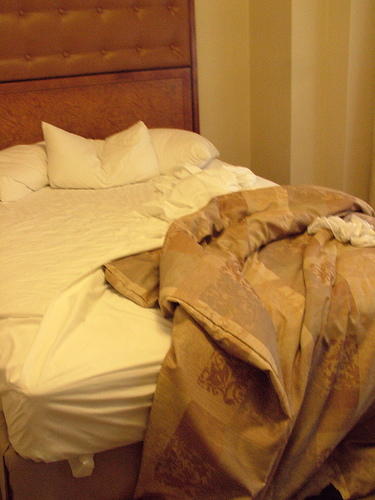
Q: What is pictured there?
A: Bed.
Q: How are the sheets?
A: Messy.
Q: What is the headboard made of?
A: Leather.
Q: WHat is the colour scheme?
A: Earth tones.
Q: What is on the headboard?
A: Buttons.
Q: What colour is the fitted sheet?
A: White.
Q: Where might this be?
A: Hotel.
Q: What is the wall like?
A: Corrugated.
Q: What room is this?
A: Bedroom.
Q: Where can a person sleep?
A: On the bed.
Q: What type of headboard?
A: Leather.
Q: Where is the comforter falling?
A: On the floor.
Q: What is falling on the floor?
A: Comforter.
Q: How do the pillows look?
A: Comfortable.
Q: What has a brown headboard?
A: The bed.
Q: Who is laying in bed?
A: There is no one.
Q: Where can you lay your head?
A: On the pillow.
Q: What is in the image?
A: Bed.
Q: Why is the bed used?
A: To sleep.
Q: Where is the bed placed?
A: In the bedroom.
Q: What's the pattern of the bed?
A: Wrinkled.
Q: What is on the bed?
A: Shirt.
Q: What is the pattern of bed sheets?
A: Multi-design sheet textile patterns.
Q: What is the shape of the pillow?
A: HEAD SHAPED INDENTATION.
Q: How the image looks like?
A: Trendy.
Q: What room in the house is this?
A: Bedroom.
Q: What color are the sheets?
A: White.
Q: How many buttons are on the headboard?
A: 10.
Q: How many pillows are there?
A: 3.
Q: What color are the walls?
A: Off white.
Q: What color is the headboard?
A: Brown.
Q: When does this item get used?
A: Night time.